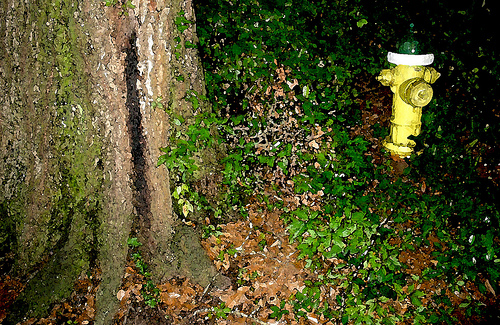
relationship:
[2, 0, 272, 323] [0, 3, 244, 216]
tree has trunk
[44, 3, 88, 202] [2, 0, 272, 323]
moss on tree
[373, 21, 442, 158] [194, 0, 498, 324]
hydrant in leaves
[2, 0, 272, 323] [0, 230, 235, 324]
tree has roots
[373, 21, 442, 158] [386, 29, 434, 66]
hydrant has top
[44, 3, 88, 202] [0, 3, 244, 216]
moss on trunk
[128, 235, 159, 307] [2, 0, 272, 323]
vine on tree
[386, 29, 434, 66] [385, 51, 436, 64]
top has stripe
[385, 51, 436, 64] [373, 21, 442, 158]
stripe on hydrant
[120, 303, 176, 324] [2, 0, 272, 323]
dirt under tree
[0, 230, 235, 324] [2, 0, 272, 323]
roots on tree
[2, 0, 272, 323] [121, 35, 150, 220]
tree has stripe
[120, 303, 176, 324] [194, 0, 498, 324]
dirt in leaves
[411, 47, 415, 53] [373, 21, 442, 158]
reflection on hydrant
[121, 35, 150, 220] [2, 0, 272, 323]
stripe on tree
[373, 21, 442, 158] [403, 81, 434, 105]
hydrant has spigot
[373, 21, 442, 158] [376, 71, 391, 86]
hydrant has spigot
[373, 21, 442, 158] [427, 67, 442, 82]
hydrant has spigot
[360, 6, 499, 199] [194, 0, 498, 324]
shadows in leaves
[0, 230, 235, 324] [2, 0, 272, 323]
roots under tree